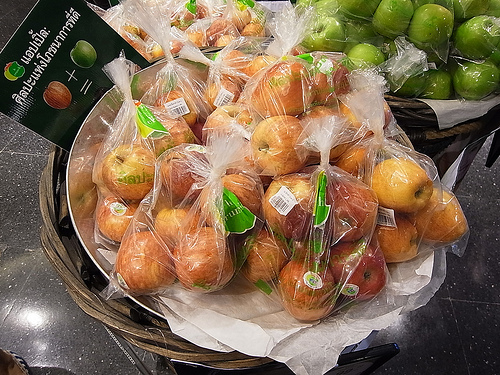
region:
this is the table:
[15, 288, 42, 314]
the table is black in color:
[25, 302, 61, 335]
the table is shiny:
[17, 309, 56, 344]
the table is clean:
[12, 292, 46, 342]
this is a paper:
[208, 314, 286, 358]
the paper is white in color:
[205, 305, 243, 336]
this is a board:
[15, 28, 87, 85]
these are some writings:
[29, 38, 61, 58]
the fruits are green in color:
[400, 7, 472, 47]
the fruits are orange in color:
[375, 175, 437, 220]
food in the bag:
[14, 39, 436, 317]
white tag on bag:
[256, 175, 312, 231]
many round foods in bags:
[52, 44, 455, 308]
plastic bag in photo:
[267, 146, 385, 251]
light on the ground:
[2, 284, 73, 340]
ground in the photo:
[2, 279, 69, 338]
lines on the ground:
[419, 272, 496, 355]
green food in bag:
[331, 6, 489, 90]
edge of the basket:
[23, 154, 101, 301]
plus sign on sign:
[53, 57, 83, 99]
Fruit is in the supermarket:
[0, 2, 497, 368]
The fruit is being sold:
[25, 0, 495, 345]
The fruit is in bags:
[0, 0, 495, 346]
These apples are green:
[306, 0, 498, 109]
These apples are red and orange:
[247, 165, 384, 312]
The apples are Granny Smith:
[296, 1, 497, 118]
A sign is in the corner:
[0, 0, 150, 149]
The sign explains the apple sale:
[0, 1, 158, 158]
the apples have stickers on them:
[272, 251, 380, 316]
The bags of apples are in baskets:
[28, 77, 498, 367]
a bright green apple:
[410, 3, 452, 49]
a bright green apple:
[455, 15, 497, 62]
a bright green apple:
[453, 60, 497, 100]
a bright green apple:
[425, 67, 454, 100]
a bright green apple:
[347, 40, 383, 67]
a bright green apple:
[371, 0, 411, 37]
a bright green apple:
[303, 18, 345, 51]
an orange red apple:
[371, 157, 434, 213]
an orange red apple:
[413, 187, 464, 242]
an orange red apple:
[371, 215, 421, 263]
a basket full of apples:
[68, 38, 413, 346]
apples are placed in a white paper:
[230, 273, 348, 373]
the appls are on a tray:
[67, 179, 178, 324]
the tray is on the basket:
[73, 156, 152, 368]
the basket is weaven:
[53, 227, 168, 372]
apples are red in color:
[111, 138, 310, 330]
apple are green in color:
[394, 4, 486, 86]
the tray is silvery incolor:
[60, 151, 121, 265]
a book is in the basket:
[19, 20, 107, 103]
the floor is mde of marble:
[21, 263, 123, 370]